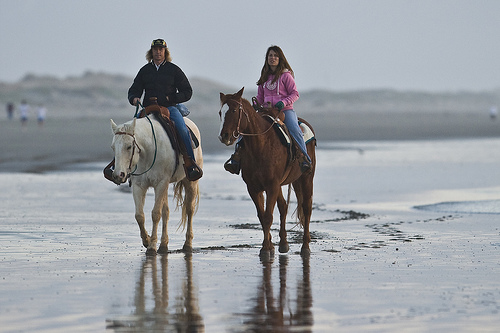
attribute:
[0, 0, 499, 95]
sky — light blue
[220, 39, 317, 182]
woman — riding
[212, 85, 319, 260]
horse — brown, white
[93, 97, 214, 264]
horse — white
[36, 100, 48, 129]
people — distant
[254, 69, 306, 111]
jacket — pink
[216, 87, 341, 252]
horse — brown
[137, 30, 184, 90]
man — wearing, riding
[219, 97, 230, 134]
forehead — white